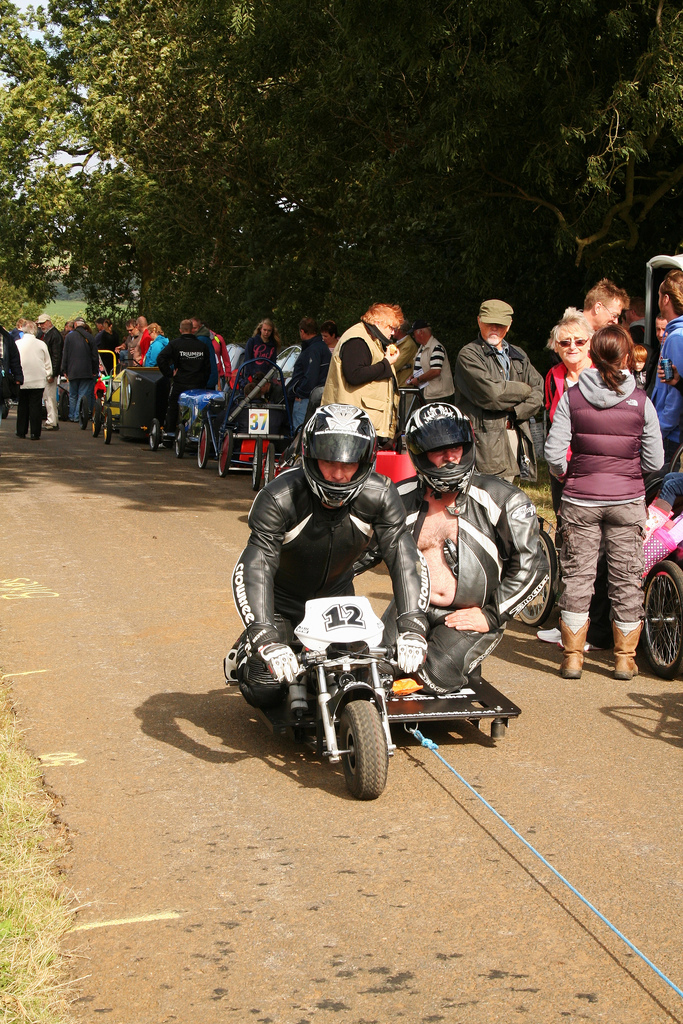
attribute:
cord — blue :
[417, 731, 671, 999]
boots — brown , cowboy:
[560, 611, 644, 676]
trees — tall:
[3, 6, 220, 314]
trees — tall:
[240, 6, 440, 332]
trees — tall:
[412, 6, 674, 324]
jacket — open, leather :
[387, 470, 542, 630]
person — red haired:
[322, 306, 397, 438]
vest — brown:
[324, 327, 395, 439]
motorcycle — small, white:
[250, 587, 405, 797]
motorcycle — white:
[288, 590, 483, 809]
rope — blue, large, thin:
[411, 729, 651, 987]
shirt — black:
[410, 339, 452, 402]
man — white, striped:
[406, 318, 452, 401]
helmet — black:
[298, 411, 376, 476]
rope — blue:
[439, 747, 600, 954]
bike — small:
[310, 596, 430, 821]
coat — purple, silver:
[548, 374, 668, 518]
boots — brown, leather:
[554, 618, 649, 691]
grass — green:
[39, 286, 124, 328]